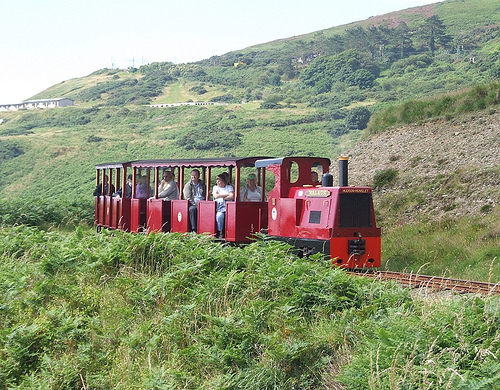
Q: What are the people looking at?
A: Wildlife.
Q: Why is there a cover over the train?
A: To keep the sun off.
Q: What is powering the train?
A: Electricity.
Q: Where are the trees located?
A: On the mountain.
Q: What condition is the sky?
A: Gray.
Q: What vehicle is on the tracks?
A: A train.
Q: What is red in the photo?
A: The train.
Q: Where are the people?
A: On the train.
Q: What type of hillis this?
A: Grassy.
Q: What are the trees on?
A: The hill.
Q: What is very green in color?
A: The hillside.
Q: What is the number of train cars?
A: Two.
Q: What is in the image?
A: Small red train.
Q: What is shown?
A: Train.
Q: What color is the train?
A: Red.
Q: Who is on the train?
A: Passengers.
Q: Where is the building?
A: Upper left.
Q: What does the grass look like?
A: Wild.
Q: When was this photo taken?
A: Daytime.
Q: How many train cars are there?
A: 2.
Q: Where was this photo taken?
A: On a hillside.